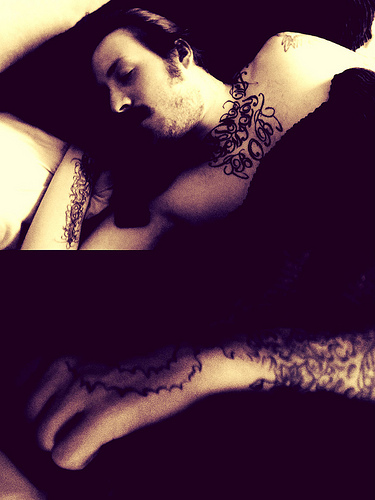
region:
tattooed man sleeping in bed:
[22, 10, 369, 229]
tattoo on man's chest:
[193, 68, 289, 184]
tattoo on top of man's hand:
[60, 335, 197, 401]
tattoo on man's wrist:
[57, 153, 91, 243]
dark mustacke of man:
[117, 103, 162, 123]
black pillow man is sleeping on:
[8, 2, 372, 150]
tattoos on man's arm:
[236, 326, 373, 396]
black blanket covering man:
[209, 65, 374, 251]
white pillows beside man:
[5, 13, 98, 238]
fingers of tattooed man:
[20, 357, 97, 468]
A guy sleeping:
[42, 33, 225, 259]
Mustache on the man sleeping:
[120, 105, 156, 122]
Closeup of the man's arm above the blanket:
[57, 336, 342, 429]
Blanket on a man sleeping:
[290, 96, 337, 252]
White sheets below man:
[8, 142, 50, 193]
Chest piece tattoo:
[205, 120, 289, 174]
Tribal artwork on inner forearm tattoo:
[61, 173, 106, 237]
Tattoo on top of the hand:
[83, 337, 188, 405]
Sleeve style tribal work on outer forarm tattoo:
[236, 332, 369, 397]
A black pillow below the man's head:
[27, 55, 97, 142]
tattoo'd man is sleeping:
[2, 1, 371, 495]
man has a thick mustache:
[108, 100, 159, 136]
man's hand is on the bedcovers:
[20, 329, 229, 482]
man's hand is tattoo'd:
[8, 310, 254, 475]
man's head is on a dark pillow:
[3, 1, 370, 165]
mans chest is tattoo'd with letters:
[189, 62, 287, 191]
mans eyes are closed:
[80, 53, 148, 97]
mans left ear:
[167, 33, 198, 76]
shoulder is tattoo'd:
[269, 27, 304, 59]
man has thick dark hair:
[77, 4, 200, 79]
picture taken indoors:
[28, 124, 360, 482]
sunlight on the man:
[12, 148, 96, 259]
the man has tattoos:
[94, 356, 364, 395]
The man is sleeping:
[101, 31, 297, 163]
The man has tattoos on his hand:
[29, 351, 221, 446]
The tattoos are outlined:
[54, 349, 265, 416]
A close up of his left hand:
[31, 359, 364, 437]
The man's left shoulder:
[253, 21, 349, 90]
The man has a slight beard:
[143, 118, 227, 136]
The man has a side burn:
[167, 61, 183, 82]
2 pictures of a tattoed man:
[12, 10, 359, 492]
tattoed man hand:
[19, 342, 211, 470]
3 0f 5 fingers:
[19, 354, 105, 468]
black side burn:
[163, 48, 183, 76]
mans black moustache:
[121, 100, 162, 121]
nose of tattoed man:
[107, 77, 128, 115]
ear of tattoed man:
[168, 35, 194, 73]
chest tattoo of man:
[201, 66, 285, 191]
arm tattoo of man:
[232, 326, 371, 400]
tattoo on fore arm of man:
[55, 153, 93, 245]